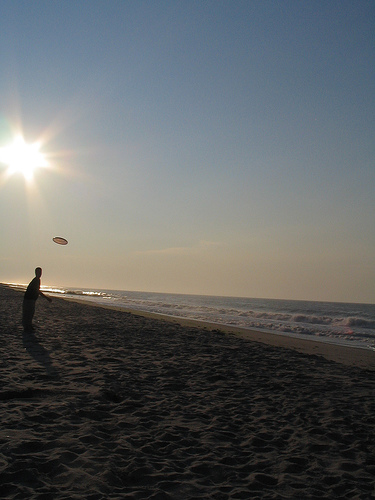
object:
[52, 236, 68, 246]
frisbee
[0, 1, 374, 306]
clouds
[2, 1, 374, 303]
sky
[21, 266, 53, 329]
person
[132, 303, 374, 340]
waves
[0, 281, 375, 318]
ocean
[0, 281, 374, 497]
footprints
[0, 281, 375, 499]
sand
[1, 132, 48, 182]
sun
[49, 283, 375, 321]
water